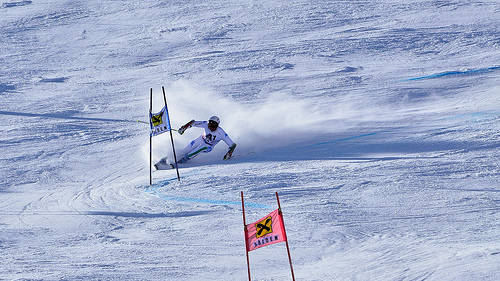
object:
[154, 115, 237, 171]
person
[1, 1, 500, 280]
snow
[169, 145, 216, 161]
snow gear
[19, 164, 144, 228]
tracks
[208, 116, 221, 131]
head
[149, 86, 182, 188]
sign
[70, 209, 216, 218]
shadow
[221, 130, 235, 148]
arm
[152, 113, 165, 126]
icon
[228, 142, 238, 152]
hand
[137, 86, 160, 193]
stick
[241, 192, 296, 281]
sign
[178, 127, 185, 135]
hand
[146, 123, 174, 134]
ski pole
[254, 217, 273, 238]
icon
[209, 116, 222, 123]
helmet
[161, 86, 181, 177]
stick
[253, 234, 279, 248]
letters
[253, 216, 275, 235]
x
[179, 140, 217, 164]
shadow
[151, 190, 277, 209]
line